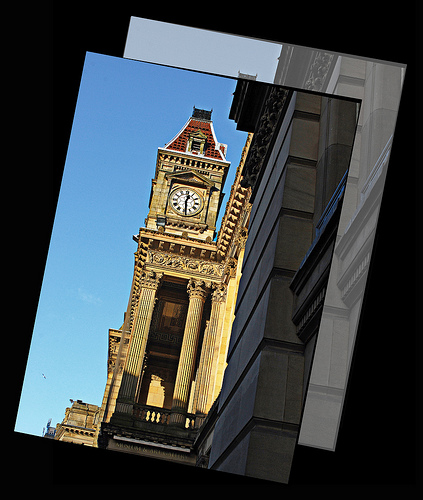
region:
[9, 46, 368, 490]
postcard featuring a clock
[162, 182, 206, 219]
face of a clock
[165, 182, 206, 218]
clock showing the time as 12:30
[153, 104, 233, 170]
red tile roof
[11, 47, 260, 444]
clear sky at midday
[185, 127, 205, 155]
small window at the top of the tower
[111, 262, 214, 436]
two support pillars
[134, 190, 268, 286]
decorative architecture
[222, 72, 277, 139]
overhang of a roof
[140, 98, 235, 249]
clock tower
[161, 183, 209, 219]
A large circular clock on the building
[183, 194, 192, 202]
The hour hand of the large clock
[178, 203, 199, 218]
The minute hand of the circular clock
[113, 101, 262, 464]
An ornate stone clock tower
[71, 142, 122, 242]
The blue sky looks clear and cloudless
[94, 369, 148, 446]
A shadow low on the building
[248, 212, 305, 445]
A grey stone wall in front of the clock tower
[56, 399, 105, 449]
Another old stone building in the distance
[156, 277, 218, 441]
Tall stone pillars on the building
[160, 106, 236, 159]
The red shingle roof of the building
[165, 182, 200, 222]
a large outdoor clock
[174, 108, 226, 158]
an orange tile roof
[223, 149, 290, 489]
a gray concrete wall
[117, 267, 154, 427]
a square column supporting a building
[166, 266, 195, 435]
a round column supporting a building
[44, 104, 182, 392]
a patch of clear blue sky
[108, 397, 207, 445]
a railing at the edge of a porch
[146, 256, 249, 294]
ornate scrollwork under the eaves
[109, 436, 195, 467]
a gold printed sign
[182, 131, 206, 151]
a small window on the top story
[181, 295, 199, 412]
the columns are made of stone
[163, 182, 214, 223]
the cloack is on the tower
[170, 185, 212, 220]
the time is 12.30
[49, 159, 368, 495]
the photo is tilted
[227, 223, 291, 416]
the wall is made of stone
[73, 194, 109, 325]
the sky is cloudless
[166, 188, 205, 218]
the clock hands are black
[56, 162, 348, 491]
the scene was taken during the day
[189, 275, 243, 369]
light is on the surface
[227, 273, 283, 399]
the wall is grey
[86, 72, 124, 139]
the sky is clear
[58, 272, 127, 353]
the sky is clear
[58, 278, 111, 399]
the sky is clear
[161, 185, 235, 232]
clock's hands are black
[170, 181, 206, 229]
clock's hands are black